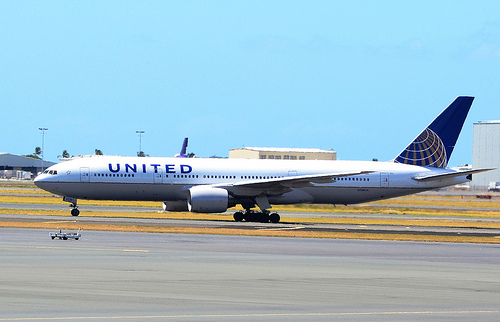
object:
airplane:
[17, 95, 494, 256]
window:
[48, 168, 60, 177]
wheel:
[65, 205, 85, 217]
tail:
[394, 91, 471, 170]